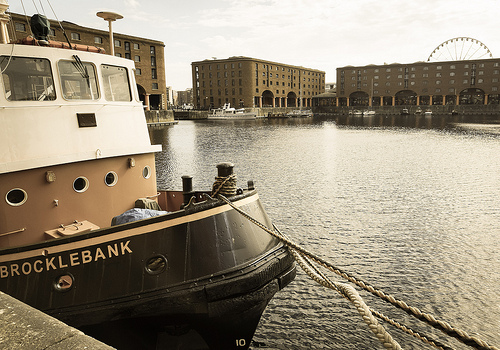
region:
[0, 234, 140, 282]
Gold writing on boat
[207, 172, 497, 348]
Rope tied to boat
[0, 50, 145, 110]
Glass windows on boat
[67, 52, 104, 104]
Windshield wiper on boat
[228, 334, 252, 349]
Number 10 on boat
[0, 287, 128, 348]
Cement dock next to boat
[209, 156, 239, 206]
Post on boat rope is tied to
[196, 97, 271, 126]
Boat docked in distance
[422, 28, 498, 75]
Ferris wheel in distance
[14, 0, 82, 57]
Rigging on top of boat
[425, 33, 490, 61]
a ferris wheel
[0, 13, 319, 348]
a docked tug boat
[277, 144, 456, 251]
calm water in a port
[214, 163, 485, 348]
ropes to dock a boat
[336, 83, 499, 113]
a portico walk way under buildings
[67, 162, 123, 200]
small round windows in a boat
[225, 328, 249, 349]
the number 10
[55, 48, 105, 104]
a windshield wipper on a boat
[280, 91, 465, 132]
docked boats along a cement wall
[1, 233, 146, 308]
Brocklebank boat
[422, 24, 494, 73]
the top of a ferris wheel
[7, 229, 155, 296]
the name of a boat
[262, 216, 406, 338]
ropes holding a boat to a dock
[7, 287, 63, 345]
a portion of a cement boat dock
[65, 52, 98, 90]
a wiper for a boat windshield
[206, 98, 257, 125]
a boat docked in the water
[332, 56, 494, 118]
a building next to a boat dock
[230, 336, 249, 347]
a number on the keel of a boat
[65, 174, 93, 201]
a porthole on a boat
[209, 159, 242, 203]
a spool for holding a rope on a boat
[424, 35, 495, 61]
the top of a Ferris Wheel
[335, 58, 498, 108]
a large retangular building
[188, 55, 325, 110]
a tan building with arches at ground level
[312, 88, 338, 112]
an awning connecting two buildings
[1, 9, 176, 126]
a building with a concrete base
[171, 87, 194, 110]
a building in shadow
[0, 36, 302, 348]
a black and white boat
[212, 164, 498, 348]
ropes to tie off a boat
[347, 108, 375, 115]
two white watercraft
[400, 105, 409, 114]
a boat sitting motionless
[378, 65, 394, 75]
window on side of building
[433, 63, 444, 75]
window on side of building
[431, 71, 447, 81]
window on side of building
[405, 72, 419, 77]
window on side of building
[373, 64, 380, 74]
window on side of building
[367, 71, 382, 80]
window on side of building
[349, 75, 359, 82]
window on side of building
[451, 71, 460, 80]
window on side of building